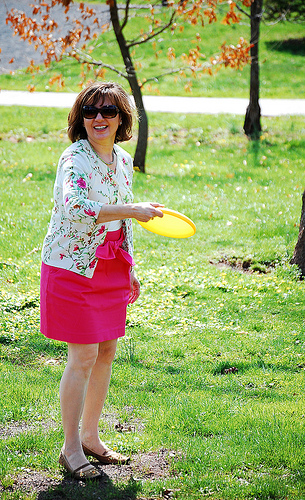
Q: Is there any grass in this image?
A: Yes, there is grass.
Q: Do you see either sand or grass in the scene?
A: Yes, there is grass.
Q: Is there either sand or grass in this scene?
A: Yes, there is grass.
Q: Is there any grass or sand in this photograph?
A: Yes, there is grass.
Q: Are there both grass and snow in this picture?
A: No, there is grass but no snow.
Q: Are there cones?
A: No, there are no cones.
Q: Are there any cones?
A: No, there are no cones.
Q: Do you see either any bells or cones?
A: No, there are no cones or bells.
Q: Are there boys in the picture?
A: No, there are no boys.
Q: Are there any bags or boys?
A: No, there are no boys or bags.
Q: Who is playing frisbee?
A: The lady is playing frisbee.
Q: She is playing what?
A: The lady is playing frisbee.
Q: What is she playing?
A: The lady is playing frisbee.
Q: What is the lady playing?
A: The lady is playing frisbee.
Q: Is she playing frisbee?
A: Yes, the lady is playing frisbee.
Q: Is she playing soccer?
A: No, the lady is playing frisbee.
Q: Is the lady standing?
A: Yes, the lady is standing.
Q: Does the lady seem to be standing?
A: Yes, the lady is standing.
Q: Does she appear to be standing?
A: Yes, the lady is standing.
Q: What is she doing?
A: The lady is standing.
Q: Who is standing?
A: The lady is standing.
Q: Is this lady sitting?
A: No, the lady is standing.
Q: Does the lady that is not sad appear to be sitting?
A: No, the lady is standing.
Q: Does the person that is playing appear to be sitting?
A: No, the lady is standing.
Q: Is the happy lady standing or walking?
A: The lady is standing.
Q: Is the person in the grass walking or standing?
A: The lady is standing.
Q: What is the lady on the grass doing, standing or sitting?
A: The lady is standing.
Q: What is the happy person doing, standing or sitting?
A: The lady is standing.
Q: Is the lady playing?
A: Yes, the lady is playing.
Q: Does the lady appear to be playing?
A: Yes, the lady is playing.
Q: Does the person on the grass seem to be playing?
A: Yes, the lady is playing.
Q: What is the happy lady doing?
A: The lady is playing.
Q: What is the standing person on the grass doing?
A: The lady is playing.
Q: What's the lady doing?
A: The lady is playing.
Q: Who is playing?
A: The lady is playing.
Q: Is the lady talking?
A: No, the lady is playing.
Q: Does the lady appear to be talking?
A: No, the lady is playing.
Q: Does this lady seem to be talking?
A: No, the lady is playing.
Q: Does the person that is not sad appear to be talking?
A: No, the lady is playing.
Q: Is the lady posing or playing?
A: The lady is playing.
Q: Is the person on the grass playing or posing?
A: The lady is playing.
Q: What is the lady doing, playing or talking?
A: The lady is playing.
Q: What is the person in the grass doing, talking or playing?
A: The lady is playing.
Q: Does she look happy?
A: Yes, the lady is happy.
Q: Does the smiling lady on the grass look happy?
A: Yes, the lady is happy.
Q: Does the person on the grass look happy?
A: Yes, the lady is happy.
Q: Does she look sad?
A: No, the lady is happy.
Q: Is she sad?
A: No, the lady is happy.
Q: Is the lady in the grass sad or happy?
A: The lady is happy.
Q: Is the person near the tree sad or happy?
A: The lady is happy.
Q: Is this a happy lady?
A: Yes, this is a happy lady.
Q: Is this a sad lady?
A: No, this is a happy lady.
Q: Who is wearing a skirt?
A: The lady is wearing a skirt.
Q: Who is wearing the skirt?
A: The lady is wearing a skirt.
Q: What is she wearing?
A: The lady is wearing a skirt.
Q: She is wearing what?
A: The lady is wearing a skirt.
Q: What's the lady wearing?
A: The lady is wearing a skirt.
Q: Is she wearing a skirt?
A: Yes, the lady is wearing a skirt.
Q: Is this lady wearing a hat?
A: No, the lady is wearing a skirt.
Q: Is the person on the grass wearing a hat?
A: No, the lady is wearing a skirt.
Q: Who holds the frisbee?
A: The lady holds the frisbee.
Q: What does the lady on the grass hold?
A: The lady holds the frisbee.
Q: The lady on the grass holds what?
A: The lady holds the frisbee.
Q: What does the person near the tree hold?
A: The lady holds the frisbee.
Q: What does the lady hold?
A: The lady holds the frisbee.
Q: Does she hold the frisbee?
A: Yes, the lady holds the frisbee.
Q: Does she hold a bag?
A: No, the lady holds the frisbee.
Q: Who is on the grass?
A: The lady is on the grass.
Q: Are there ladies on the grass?
A: Yes, there is a lady on the grass.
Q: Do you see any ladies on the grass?
A: Yes, there is a lady on the grass.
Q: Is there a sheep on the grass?
A: No, there is a lady on the grass.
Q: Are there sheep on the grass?
A: No, there is a lady on the grass.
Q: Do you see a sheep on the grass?
A: No, there is a lady on the grass.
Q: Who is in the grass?
A: The lady is in the grass.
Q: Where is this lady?
A: The lady is in the grass.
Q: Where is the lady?
A: The lady is in the grass.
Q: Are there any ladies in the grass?
A: Yes, there is a lady in the grass.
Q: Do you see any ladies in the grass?
A: Yes, there is a lady in the grass.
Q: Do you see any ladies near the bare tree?
A: Yes, there is a lady near the tree.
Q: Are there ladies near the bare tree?
A: Yes, there is a lady near the tree.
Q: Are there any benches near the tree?
A: No, there is a lady near the tree.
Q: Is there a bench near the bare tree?
A: No, there is a lady near the tree.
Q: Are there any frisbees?
A: Yes, there is a frisbee.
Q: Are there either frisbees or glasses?
A: Yes, there is a frisbee.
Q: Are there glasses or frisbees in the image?
A: Yes, there is a frisbee.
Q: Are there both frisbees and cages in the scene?
A: No, there is a frisbee but no cages.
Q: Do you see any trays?
A: No, there are no trays.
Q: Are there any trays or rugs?
A: No, there are no trays or rugs.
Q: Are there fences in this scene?
A: No, there are no fences.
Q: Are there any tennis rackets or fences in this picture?
A: No, there are no fences or tennis rackets.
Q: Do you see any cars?
A: No, there are no cars.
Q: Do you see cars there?
A: No, there are no cars.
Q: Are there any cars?
A: No, there are no cars.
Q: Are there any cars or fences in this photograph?
A: No, there are no cars or fences.